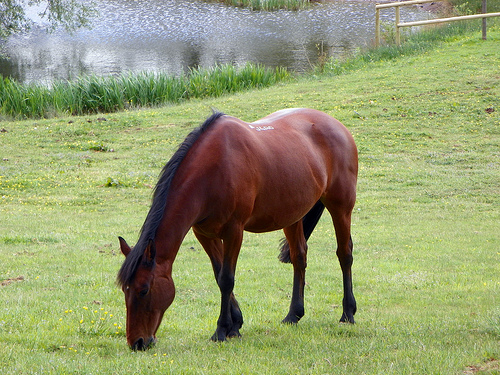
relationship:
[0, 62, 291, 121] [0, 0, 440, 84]
weeds next to pond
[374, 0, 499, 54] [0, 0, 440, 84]
railing next to pond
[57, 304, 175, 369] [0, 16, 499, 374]
flowers in grass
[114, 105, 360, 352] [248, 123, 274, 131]
horse has brand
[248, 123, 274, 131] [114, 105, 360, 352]
brand on horse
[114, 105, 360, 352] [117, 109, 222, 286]
horse has mane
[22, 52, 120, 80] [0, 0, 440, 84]
reflection in pond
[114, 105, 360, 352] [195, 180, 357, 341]
horse has legs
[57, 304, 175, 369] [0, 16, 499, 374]
flowers on grass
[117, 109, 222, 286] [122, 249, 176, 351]
mane on head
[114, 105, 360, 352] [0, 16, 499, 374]
horse eating grass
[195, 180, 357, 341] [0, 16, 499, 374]
legs on grass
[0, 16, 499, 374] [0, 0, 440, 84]
grass near pond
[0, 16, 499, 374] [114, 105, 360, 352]
grass under horse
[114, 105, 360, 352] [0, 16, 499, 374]
horse in grass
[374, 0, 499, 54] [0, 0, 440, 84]
railing near pond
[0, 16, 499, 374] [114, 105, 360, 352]
grass next to horse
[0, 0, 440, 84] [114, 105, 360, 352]
pond behind horse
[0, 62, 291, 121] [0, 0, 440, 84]
weeds near pond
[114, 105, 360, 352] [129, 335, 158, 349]
horse has nose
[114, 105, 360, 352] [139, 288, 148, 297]
horse has left eye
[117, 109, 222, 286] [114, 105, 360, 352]
mane on horse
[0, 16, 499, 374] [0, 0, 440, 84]
grass next to pond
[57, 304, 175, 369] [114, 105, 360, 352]
flowers next to horse